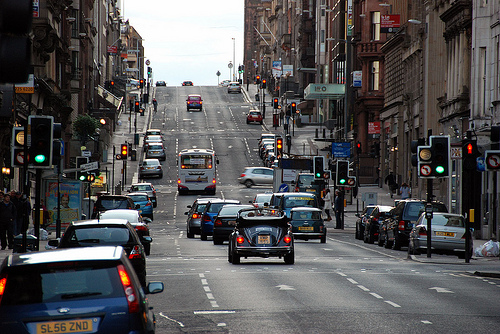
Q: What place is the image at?
A: It is at the street.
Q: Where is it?
A: This is at the street.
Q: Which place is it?
A: It is a street.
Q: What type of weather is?
A: It is cloudy.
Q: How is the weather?
A: It is cloudy.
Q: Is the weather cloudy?
A: Yes, it is cloudy.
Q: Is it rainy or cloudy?
A: It is cloudy.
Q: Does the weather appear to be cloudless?
A: No, it is cloudy.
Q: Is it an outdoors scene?
A: Yes, it is outdoors.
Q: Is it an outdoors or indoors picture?
A: It is outdoors.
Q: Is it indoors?
A: No, it is outdoors.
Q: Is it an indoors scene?
A: No, it is outdoors.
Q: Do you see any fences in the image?
A: No, there are no fences.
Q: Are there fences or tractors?
A: No, there are no fences or tractors.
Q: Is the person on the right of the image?
A: Yes, the person is on the right of the image.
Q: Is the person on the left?
A: No, the person is on the right of the image.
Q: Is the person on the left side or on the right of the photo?
A: The person is on the right of the image.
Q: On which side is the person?
A: The person is on the right of the image.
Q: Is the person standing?
A: Yes, the person is standing.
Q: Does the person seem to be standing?
A: Yes, the person is standing.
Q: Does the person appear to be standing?
A: Yes, the person is standing.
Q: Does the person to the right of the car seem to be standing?
A: Yes, the person is standing.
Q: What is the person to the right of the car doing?
A: The person is standing.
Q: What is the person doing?
A: The person is standing.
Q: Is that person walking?
A: No, the person is standing.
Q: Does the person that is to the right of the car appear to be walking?
A: No, the person is standing.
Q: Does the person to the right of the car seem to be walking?
A: No, the person is standing.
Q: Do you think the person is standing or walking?
A: The person is standing.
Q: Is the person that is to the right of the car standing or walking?
A: The person is standing.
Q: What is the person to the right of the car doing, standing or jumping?
A: The person is standing.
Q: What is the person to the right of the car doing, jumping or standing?
A: The person is standing.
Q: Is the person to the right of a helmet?
A: No, the person is to the right of the car.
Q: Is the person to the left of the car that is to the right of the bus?
A: No, the person is to the right of the car.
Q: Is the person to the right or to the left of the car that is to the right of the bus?
A: The person is to the right of the car.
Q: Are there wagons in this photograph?
A: No, there are no wagons.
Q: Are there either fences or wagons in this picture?
A: No, there are no wagons or fences.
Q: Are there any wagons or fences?
A: No, there are no wagons or fences.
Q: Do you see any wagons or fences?
A: No, there are no wagons or fences.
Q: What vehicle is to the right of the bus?
A: The vehicle is a car.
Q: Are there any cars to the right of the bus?
A: Yes, there is a car to the right of the bus.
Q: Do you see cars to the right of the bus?
A: Yes, there is a car to the right of the bus.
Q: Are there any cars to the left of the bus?
A: No, the car is to the right of the bus.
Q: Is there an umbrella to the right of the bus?
A: No, there is a car to the right of the bus.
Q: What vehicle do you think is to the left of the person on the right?
A: The vehicle is a car.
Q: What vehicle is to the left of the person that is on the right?
A: The vehicle is a car.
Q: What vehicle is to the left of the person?
A: The vehicle is a car.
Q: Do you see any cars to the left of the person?
A: Yes, there is a car to the left of the person.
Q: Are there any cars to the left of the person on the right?
A: Yes, there is a car to the left of the person.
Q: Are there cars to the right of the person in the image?
A: No, the car is to the left of the person.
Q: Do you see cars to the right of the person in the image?
A: No, the car is to the left of the person.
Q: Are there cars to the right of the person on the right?
A: No, the car is to the left of the person.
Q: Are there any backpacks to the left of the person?
A: No, there is a car to the left of the person.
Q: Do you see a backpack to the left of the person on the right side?
A: No, there is a car to the left of the person.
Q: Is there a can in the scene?
A: No, there are no cans.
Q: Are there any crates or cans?
A: No, there are no cans or crates.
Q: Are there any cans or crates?
A: No, there are no cans or crates.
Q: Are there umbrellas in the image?
A: No, there are no umbrellas.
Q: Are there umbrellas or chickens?
A: No, there are no umbrellas or chickens.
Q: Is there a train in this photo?
A: No, there are no trains.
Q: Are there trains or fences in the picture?
A: No, there are no trains or fences.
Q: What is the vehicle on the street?
A: The vehicle is a car.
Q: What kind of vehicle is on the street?
A: The vehicle is a car.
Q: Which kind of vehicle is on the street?
A: The vehicle is a car.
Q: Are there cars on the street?
A: Yes, there is a car on the street.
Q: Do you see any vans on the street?
A: No, there is a car on the street.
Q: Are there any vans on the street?
A: No, there is a car on the street.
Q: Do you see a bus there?
A: Yes, there is a bus.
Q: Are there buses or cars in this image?
A: Yes, there is a bus.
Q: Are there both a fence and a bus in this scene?
A: No, there is a bus but no fences.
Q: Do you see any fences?
A: No, there are no fences.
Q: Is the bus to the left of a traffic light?
A: No, the bus is to the left of the car.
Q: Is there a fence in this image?
A: No, there are no fences.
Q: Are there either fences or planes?
A: No, there are no fences or planes.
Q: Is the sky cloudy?
A: Yes, the sky is cloudy.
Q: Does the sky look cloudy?
A: Yes, the sky is cloudy.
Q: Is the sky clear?
A: No, the sky is cloudy.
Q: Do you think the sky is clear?
A: No, the sky is cloudy.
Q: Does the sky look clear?
A: No, the sky is cloudy.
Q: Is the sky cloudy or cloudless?
A: The sky is cloudy.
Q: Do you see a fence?
A: No, there are no fences.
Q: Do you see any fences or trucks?
A: No, there are no fences or trucks.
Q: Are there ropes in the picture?
A: No, there are no ropes.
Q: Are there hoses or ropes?
A: No, there are no ropes or hoses.